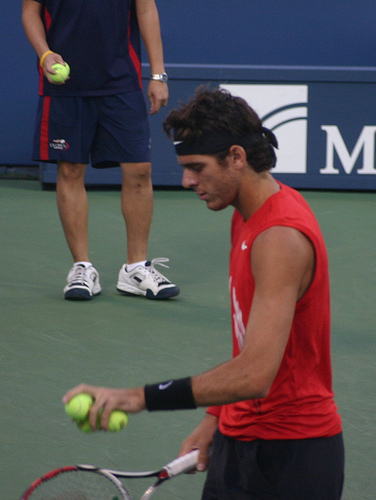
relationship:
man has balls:
[113, 95, 351, 471] [57, 366, 121, 439]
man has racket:
[113, 95, 351, 471] [47, 455, 207, 496]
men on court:
[50, 31, 343, 347] [79, 310, 170, 347]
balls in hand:
[57, 366, 121, 439] [90, 396, 163, 419]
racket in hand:
[47, 455, 207, 496] [90, 396, 163, 419]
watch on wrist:
[131, 60, 195, 90] [33, 49, 73, 66]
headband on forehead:
[163, 110, 314, 179] [159, 120, 214, 134]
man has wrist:
[113, 95, 351, 471] [33, 49, 73, 66]